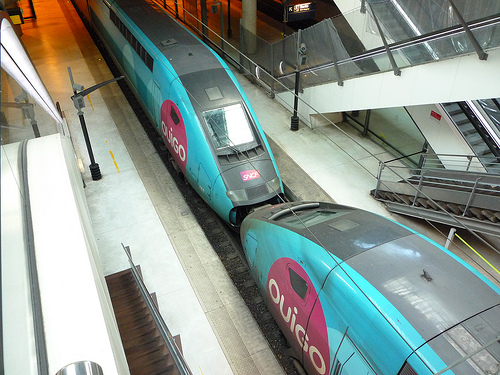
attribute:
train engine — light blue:
[258, 208, 499, 361]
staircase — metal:
[89, 237, 168, 357]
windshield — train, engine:
[202, 100, 254, 150]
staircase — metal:
[370, 152, 498, 237]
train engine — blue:
[114, 14, 289, 231]